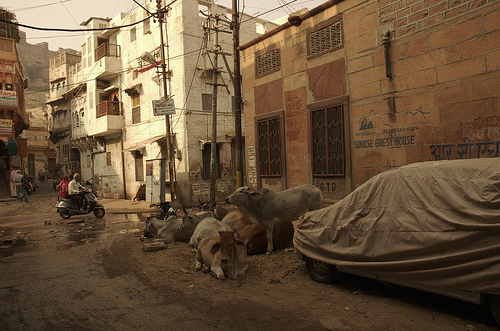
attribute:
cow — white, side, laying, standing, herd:
[197, 158, 346, 268]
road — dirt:
[41, 229, 160, 320]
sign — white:
[114, 75, 182, 146]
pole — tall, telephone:
[224, 26, 261, 183]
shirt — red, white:
[48, 164, 77, 209]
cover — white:
[277, 147, 492, 286]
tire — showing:
[270, 247, 341, 293]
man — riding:
[79, 172, 88, 184]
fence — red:
[293, 111, 341, 215]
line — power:
[201, 0, 278, 45]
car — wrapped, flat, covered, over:
[264, 125, 480, 313]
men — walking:
[20, 159, 34, 195]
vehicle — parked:
[307, 105, 499, 295]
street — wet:
[29, 100, 371, 331]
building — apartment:
[209, 6, 450, 218]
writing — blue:
[366, 112, 435, 157]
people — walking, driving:
[3, 159, 51, 209]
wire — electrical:
[231, 5, 279, 50]